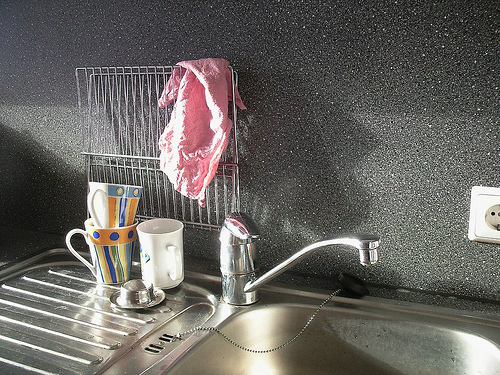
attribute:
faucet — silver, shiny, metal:
[220, 213, 380, 304]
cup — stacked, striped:
[66, 218, 138, 283]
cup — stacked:
[88, 181, 142, 226]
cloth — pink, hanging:
[158, 58, 246, 206]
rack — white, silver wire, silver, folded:
[77, 67, 238, 231]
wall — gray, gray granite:
[0, 0, 499, 303]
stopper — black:
[338, 274, 367, 294]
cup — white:
[137, 217, 184, 288]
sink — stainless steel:
[148, 303, 499, 374]